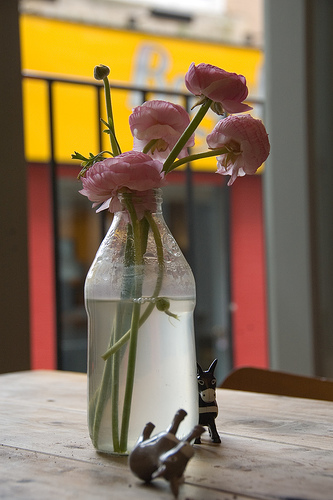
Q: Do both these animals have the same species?
A: Yes, all the animals are donkeys.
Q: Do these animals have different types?
A: No, all the animals are donkeys.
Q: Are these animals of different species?
A: No, all the animals are donkeys.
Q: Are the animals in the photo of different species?
A: No, all the animals are donkeys.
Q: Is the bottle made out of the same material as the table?
A: No, the bottle is made of glass and the table is made of wood.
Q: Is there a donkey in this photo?
A: Yes, there is a donkey.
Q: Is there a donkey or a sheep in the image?
A: Yes, there is a donkey.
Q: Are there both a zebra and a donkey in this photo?
A: No, there is a donkey but no zebras.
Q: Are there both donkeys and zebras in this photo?
A: No, there is a donkey but no zebras.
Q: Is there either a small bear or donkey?
A: Yes, there is a small donkey.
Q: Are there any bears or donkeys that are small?
A: Yes, the donkey is small.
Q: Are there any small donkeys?
A: Yes, there is a small donkey.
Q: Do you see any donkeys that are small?
A: Yes, there is a donkey that is small.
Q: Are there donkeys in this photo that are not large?
A: Yes, there is a small donkey.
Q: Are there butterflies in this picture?
A: No, there are no butterflies.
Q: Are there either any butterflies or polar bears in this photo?
A: No, there are no butterflies or polar bears.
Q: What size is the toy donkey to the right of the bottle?
A: The donkey is small.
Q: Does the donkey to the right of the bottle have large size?
A: No, the donkey is small.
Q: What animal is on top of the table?
A: The donkey is on top of the table.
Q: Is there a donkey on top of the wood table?
A: Yes, there is a donkey on top of the table.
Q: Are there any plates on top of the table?
A: No, there is a donkey on top of the table.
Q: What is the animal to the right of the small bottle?
A: The animal is a donkey.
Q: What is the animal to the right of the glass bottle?
A: The animal is a donkey.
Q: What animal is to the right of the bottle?
A: The animal is a donkey.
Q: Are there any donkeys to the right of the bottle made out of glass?
A: Yes, there is a donkey to the right of the bottle.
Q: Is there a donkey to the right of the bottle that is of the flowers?
A: Yes, there is a donkey to the right of the bottle.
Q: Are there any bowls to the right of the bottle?
A: No, there is a donkey to the right of the bottle.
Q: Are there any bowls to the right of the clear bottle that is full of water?
A: No, there is a donkey to the right of the bottle.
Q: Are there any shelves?
A: No, there are no shelves.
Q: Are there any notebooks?
A: No, there are no notebooks.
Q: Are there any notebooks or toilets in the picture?
A: No, there are no notebooks or toilets.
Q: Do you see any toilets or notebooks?
A: No, there are no notebooks or toilets.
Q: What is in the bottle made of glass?
A: The flowers are in the bottle.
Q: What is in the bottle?
A: The flowers are in the bottle.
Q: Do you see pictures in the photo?
A: No, there are no pictures.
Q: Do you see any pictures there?
A: No, there are no pictures.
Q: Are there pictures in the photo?
A: No, there are no pictures.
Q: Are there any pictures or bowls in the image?
A: No, there are no pictures or bowls.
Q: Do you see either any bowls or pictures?
A: No, there are no pictures or bowls.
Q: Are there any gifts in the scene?
A: No, there are no gifts.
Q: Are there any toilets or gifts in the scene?
A: No, there are no gifts or toilets.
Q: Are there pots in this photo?
A: No, there are no pots.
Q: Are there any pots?
A: No, there are no pots.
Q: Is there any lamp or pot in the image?
A: No, there are no pots or lamps.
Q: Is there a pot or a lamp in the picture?
A: No, there are no pots or lamps.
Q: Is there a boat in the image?
A: No, there are no boats.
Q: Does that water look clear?
A: Yes, the water is clear.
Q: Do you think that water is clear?
A: Yes, the water is clear.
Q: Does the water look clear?
A: Yes, the water is clear.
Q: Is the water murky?
A: No, the water is clear.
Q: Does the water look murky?
A: No, the water is clear.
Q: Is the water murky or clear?
A: The water is clear.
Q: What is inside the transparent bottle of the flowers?
A: The water is inside the bottle.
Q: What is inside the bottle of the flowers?
A: The water is inside the bottle.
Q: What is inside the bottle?
A: The water is inside the bottle.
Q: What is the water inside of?
A: The water is inside the bottle.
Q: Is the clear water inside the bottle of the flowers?
A: Yes, the water is inside the bottle.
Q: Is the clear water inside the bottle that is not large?
A: Yes, the water is inside the bottle.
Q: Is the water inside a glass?
A: No, the water is inside the bottle.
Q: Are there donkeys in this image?
A: Yes, there is a donkey.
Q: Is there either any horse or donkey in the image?
A: Yes, there is a donkey.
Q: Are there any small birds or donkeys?
A: Yes, there is a small donkey.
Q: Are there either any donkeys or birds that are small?
A: Yes, the donkey is small.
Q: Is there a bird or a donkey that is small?
A: Yes, the donkey is small.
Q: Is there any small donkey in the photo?
A: Yes, there is a small donkey.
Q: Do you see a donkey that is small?
A: Yes, there is a donkey that is small.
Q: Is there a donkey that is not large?
A: Yes, there is a small donkey.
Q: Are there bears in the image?
A: No, there are no bears.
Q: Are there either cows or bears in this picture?
A: No, there are no bears or cows.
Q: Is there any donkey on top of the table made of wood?
A: Yes, there is a donkey on top of the table.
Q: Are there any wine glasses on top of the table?
A: No, there is a donkey on top of the table.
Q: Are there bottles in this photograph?
A: Yes, there is a bottle.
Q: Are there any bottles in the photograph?
A: Yes, there is a bottle.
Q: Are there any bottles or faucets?
A: Yes, there is a bottle.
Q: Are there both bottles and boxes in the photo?
A: No, there is a bottle but no boxes.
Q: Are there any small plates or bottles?
A: Yes, there is a small bottle.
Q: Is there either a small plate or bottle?
A: Yes, there is a small bottle.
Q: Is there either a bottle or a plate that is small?
A: Yes, the bottle is small.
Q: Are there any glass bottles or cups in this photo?
A: Yes, there is a glass bottle.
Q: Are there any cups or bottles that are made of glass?
A: Yes, the bottle is made of glass.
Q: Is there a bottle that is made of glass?
A: Yes, there is a bottle that is made of glass.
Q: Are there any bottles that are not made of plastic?
A: Yes, there is a bottle that is made of glass.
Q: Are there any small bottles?
A: Yes, there is a small bottle.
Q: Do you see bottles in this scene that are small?
A: Yes, there is a bottle that is small.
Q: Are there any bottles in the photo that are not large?
A: Yes, there is a small bottle.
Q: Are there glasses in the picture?
A: No, there are no glasses.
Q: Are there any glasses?
A: No, there are no glasses.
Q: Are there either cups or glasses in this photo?
A: No, there are no glasses or cups.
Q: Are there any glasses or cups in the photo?
A: No, there are no glasses or cups.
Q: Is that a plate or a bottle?
A: That is a bottle.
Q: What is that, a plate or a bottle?
A: That is a bottle.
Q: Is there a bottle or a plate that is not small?
A: No, there is a bottle but it is small.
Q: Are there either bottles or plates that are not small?
A: No, there is a bottle but it is small.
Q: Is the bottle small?
A: Yes, the bottle is small.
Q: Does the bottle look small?
A: Yes, the bottle is small.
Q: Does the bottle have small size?
A: Yes, the bottle is small.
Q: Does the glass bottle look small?
A: Yes, the bottle is small.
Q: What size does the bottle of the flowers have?
A: The bottle has small size.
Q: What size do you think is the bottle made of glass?
A: The bottle is small.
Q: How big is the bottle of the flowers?
A: The bottle is small.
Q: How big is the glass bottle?
A: The bottle is small.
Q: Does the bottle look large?
A: No, the bottle is small.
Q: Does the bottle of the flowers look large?
A: No, the bottle is small.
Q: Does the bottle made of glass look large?
A: No, the bottle is small.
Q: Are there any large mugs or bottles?
A: No, there is a bottle but it is small.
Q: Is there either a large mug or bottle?
A: No, there is a bottle but it is small.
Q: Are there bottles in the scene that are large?
A: No, there is a bottle but it is small.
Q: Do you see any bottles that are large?
A: No, there is a bottle but it is small.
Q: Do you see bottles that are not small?
A: No, there is a bottle but it is small.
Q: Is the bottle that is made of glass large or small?
A: The bottle is small.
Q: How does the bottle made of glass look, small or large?
A: The bottle is small.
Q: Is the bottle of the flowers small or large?
A: The bottle is small.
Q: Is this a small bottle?
A: Yes, this is a small bottle.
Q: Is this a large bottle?
A: No, this is a small bottle.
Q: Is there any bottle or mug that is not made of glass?
A: No, there is a bottle but it is made of glass.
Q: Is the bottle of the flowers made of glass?
A: Yes, the bottle is made of glass.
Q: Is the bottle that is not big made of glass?
A: Yes, the bottle is made of glass.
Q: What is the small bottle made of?
A: The bottle is made of glass.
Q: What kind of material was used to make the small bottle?
A: The bottle is made of glass.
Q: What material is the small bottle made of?
A: The bottle is made of glass.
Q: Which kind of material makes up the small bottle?
A: The bottle is made of glass.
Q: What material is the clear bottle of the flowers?
A: The bottle is made of glass.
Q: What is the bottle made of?
A: The bottle is made of glass.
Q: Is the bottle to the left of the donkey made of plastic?
A: No, the bottle is made of glass.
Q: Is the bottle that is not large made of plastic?
A: No, the bottle is made of glass.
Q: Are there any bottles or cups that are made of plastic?
A: No, there is a bottle but it is made of glass.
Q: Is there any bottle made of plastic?
A: No, there is a bottle but it is made of glass.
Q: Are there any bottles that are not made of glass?
A: No, there is a bottle but it is made of glass.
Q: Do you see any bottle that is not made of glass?
A: No, there is a bottle but it is made of glass.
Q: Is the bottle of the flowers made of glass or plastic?
A: The bottle is made of glass.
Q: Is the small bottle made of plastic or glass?
A: The bottle is made of glass.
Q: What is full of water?
A: The bottle is full of water.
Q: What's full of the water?
A: The bottle is full of water.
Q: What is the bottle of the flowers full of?
A: The bottle is full of water.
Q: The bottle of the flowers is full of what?
A: The bottle is full of water.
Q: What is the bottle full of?
A: The bottle is full of water.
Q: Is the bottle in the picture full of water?
A: Yes, the bottle is full of water.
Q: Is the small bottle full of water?
A: Yes, the bottle is full of water.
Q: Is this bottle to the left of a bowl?
A: No, the bottle is to the left of the donkey.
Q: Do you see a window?
A: Yes, there is a window.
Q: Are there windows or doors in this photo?
A: Yes, there is a window.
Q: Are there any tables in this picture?
A: Yes, there is a table.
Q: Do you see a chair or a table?
A: Yes, there is a table.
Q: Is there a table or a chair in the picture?
A: Yes, there is a table.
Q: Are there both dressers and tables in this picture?
A: No, there is a table but no dressers.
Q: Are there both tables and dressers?
A: No, there is a table but no dressers.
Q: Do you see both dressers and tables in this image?
A: No, there is a table but no dressers.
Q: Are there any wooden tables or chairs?
A: Yes, there is a wood table.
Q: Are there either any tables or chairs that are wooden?
A: Yes, the table is wooden.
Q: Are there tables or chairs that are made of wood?
A: Yes, the table is made of wood.